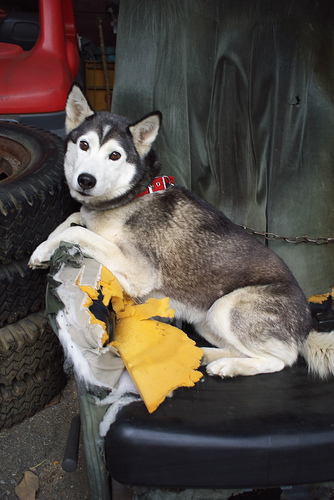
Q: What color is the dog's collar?
A: Red.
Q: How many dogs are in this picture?
A: One.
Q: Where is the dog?
A: On the chair.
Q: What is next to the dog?
A: A stack of tires.